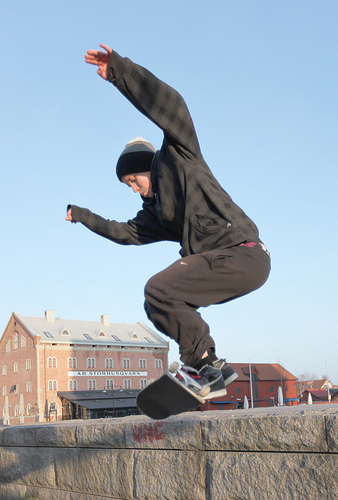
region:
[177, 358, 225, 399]
it is the show of the boy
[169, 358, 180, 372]
white wheel on the skateboard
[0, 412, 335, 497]
it is a stone wall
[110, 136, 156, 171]
boy is wearing a beanie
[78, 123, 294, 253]
boy is wearing a black sweater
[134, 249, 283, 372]
boy in black pants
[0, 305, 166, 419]
a large building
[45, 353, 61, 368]
a window in the building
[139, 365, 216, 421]
skateboard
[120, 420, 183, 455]
red writing on the stone wall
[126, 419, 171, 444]
Grafitti on rock wall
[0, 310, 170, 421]
Large brick building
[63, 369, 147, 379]
Business name on brick building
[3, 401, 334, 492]
Grey rock wall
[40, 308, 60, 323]
Chimney on roof of building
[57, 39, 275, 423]
Skateboarder performing aerial trick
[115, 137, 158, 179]
Knitted hat on skateboarder's head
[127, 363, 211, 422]
Inverted skateboard in air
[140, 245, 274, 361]
Black pants on skateboarder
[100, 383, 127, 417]
Street lamp poles in front of building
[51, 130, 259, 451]
the man is skateboarding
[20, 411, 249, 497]
fence made of stone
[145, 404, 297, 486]
fence made of stone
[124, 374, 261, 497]
fence made of stone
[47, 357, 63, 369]
window on side of building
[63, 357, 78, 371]
window on side of building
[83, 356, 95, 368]
window on side of building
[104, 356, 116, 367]
window on side of building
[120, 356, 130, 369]
window on side of building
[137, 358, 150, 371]
window on side of building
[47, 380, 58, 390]
window on side of building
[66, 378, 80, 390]
window on side of building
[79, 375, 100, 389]
window on side of building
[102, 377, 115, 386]
window on side of building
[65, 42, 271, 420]
Young person riding skateboard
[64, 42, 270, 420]
Person jumping skateboard near stone wall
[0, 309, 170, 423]
Large multi-storied brick building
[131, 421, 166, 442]
Red graffiti on stone wall just below skateboard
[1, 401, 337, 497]
Stone or faux stone wall showing rectangular pattern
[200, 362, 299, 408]
Red building with some sort of blue items on wall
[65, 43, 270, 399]
Person wearing knitted cap, gray plaid shirt, gray pants, and sneakers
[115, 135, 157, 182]
Black, gray, and white striped knitted hat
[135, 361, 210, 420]
Upside down gray or brown skateboard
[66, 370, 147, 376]
White sign with black letters on brick building